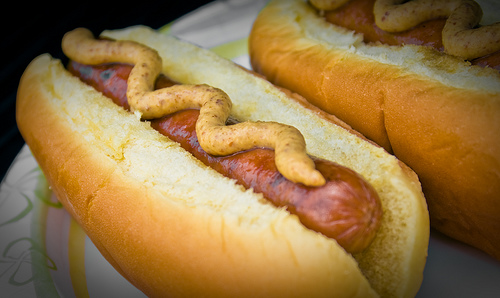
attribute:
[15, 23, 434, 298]
hot dog — cooked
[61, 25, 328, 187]
mustard — squiggle, line-shaped, spicy, yellow, stone ground, in line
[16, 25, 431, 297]
bun — hot dog bun, white bread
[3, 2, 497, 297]
plate — white, paper, yellow, round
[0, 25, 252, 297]
design — green, yellow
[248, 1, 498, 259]
bun — tan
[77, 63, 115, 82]
grill mark — dark, brown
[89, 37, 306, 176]
seasoning — brown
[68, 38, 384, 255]
hot dog — grilled, brown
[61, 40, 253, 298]
line — yellow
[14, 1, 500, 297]
buns — white bread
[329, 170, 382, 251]
end — round